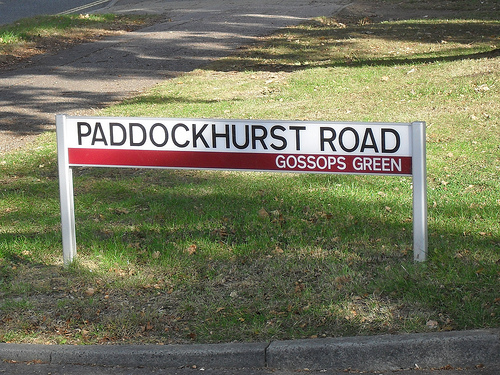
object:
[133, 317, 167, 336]
leaves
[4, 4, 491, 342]
grass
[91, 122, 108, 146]
letter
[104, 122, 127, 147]
letter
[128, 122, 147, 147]
letter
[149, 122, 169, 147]
letter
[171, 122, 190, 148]
letter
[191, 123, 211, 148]
letter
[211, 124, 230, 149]
letter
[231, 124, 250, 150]
letter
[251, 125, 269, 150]
letter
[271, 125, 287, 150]
letter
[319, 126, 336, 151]
letter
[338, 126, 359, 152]
letter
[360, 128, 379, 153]
letter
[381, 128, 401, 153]
letter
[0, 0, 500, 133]
shadows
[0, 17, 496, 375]
ground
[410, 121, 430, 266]
pole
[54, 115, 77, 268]
pole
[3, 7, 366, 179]
road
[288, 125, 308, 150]
black letter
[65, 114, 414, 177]
sign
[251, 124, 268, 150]
black letter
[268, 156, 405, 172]
bottom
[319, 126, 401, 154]
road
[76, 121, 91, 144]
letter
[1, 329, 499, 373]
curb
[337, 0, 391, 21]
dirt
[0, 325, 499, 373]
street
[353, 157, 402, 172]
text